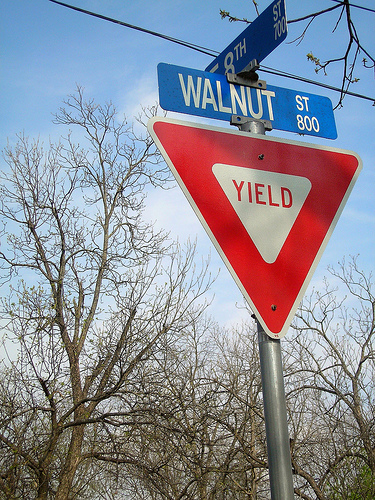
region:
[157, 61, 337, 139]
blue and white street sign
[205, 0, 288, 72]
blue and white street sign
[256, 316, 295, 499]
silver metal street sign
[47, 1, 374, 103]
black electricity wire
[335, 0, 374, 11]
black electricity wire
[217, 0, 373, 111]
tree branch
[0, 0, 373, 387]
cloudy blue sky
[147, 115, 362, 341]
red and white yield sign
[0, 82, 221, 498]
tree growing behind yield sign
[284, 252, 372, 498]
tree growing behind yield sign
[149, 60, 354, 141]
"Walnut" on the sign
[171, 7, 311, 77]
"58th" on the sign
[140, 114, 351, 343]
This is a yield sign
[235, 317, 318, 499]
The pole is silver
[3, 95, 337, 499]
The trees are bare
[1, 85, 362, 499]
A ton of trees in the background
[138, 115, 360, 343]
Sign is red and white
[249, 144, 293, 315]
Nails in the sign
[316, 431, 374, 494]
Leaves in the corner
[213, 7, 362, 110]
Tree branch in the air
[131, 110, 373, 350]
a triangular sign on a pole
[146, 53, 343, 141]
a blue sign above a red sign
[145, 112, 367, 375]
a yield sign on a pole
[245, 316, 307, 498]
a pole is gray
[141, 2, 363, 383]
three signs on a pole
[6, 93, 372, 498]
trees behind the signs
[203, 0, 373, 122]
a branch over the signs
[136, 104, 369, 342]
the word says "Yield"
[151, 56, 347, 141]
sign has white words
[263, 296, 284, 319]
a bolt on a sig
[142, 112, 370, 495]
Red and white YIELD sign.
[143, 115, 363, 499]
Red and white sign on a silver pole.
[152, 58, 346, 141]
Blue street sign above a YIELD sign.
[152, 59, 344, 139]
Blue sign that reads WALNUT ST.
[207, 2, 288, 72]
Blue sign with the number 700.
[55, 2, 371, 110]
Electric lines in the air.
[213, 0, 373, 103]
Tree branch with buds growing.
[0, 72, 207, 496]
Trees behind a street sign.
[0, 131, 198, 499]
Bare limbs on a tree.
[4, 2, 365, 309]
Blue sky with white clouds.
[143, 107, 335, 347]
Yield sign on a pole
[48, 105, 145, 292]
Branches of a tree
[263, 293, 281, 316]
Screw on a yield sign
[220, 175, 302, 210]
Red letters on white sign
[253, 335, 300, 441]
Silver pole for sign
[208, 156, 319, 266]
White triangle on a sign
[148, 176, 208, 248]
Blue sky above sign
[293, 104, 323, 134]
White numbers on a blue sign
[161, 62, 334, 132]
Blue street sign on a pole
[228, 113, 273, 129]
Metal holder for blue sign